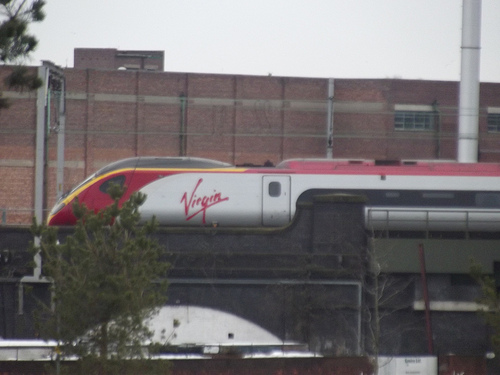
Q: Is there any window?
A: Yes, there is a window.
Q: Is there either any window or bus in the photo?
A: Yes, there is a window.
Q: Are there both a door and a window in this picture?
A: Yes, there are both a window and a door.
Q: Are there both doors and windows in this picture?
A: Yes, there are both a window and a door.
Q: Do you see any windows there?
A: Yes, there is a window.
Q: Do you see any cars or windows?
A: Yes, there is a window.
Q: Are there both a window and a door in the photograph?
A: Yes, there are both a window and a door.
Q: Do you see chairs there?
A: No, there are no chairs.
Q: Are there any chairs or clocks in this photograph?
A: No, there are no chairs or clocks.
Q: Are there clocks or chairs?
A: No, there are no chairs or clocks.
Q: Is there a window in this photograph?
A: Yes, there are windows.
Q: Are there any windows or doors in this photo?
A: Yes, there are windows.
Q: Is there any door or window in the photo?
A: Yes, there are windows.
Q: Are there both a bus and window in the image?
A: No, there are windows but no buses.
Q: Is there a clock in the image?
A: No, there are no clocks.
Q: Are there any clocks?
A: No, there are no clocks.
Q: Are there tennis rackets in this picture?
A: No, there are no tennis rackets.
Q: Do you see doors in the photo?
A: Yes, there is a door.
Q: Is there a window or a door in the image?
A: Yes, there is a door.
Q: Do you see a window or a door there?
A: Yes, there is a door.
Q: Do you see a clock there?
A: No, there are no clocks.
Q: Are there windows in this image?
A: Yes, there is a window.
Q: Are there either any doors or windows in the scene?
A: Yes, there is a window.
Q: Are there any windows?
A: Yes, there is a window.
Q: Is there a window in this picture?
A: Yes, there is a window.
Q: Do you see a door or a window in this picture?
A: Yes, there is a window.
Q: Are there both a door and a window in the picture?
A: Yes, there are both a window and a door.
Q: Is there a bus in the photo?
A: No, there are no buses.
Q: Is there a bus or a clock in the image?
A: No, there are no buses or clocks.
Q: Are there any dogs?
A: No, there are no dogs.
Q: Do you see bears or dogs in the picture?
A: No, there are no dogs or bears.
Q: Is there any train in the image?
A: Yes, there is a train.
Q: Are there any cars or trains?
A: Yes, there is a train.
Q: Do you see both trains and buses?
A: No, there is a train but no buses.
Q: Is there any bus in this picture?
A: No, there are no buses.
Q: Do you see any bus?
A: No, there are no buses.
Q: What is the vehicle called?
A: The vehicle is a train.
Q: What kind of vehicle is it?
A: The vehicle is a train.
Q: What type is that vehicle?
A: This is a train.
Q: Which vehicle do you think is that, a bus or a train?
A: This is a train.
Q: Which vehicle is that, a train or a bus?
A: This is a train.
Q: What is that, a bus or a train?
A: That is a train.